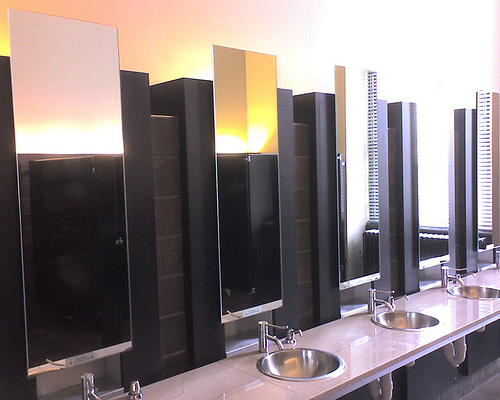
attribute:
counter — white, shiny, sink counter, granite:
[105, 266, 500, 400]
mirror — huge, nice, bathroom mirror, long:
[9, 6, 132, 378]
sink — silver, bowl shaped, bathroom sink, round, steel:
[257, 346, 345, 383]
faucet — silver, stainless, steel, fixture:
[258, 320, 289, 352]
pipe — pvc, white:
[444, 337, 469, 367]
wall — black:
[1, 56, 36, 400]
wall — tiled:
[149, 113, 194, 377]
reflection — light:
[217, 125, 276, 156]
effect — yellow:
[215, 46, 278, 153]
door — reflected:
[30, 155, 131, 367]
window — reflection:
[416, 104, 451, 231]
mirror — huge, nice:
[212, 44, 282, 326]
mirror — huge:
[332, 66, 379, 293]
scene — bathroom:
[0, 2, 499, 399]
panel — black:
[294, 123, 319, 331]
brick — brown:
[151, 114, 185, 157]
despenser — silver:
[286, 326, 304, 344]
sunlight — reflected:
[345, 69, 371, 241]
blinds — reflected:
[366, 70, 380, 223]